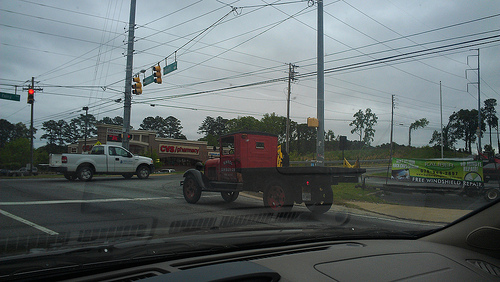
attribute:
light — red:
[26, 79, 36, 104]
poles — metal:
[310, 0, 340, 147]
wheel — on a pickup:
[134, 162, 151, 179]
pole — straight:
[313, 0, 324, 157]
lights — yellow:
[126, 57, 172, 98]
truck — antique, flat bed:
[177, 132, 361, 217]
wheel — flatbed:
[174, 170, 212, 197]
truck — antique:
[163, 120, 340, 215]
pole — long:
[309, 45, 336, 117]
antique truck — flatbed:
[178, 131, 369, 216]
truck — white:
[48, 143, 155, 183]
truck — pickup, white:
[42, 138, 156, 182]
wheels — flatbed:
[261, 185, 336, 216]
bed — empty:
[243, 164, 365, 175]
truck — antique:
[193, 144, 340, 188]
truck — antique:
[197, 141, 332, 204]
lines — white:
[3, 195, 172, 233]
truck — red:
[166, 113, 366, 223]